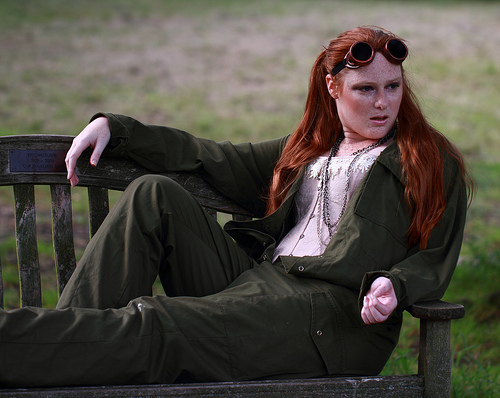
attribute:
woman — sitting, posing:
[2, 27, 468, 390]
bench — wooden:
[2, 131, 468, 396]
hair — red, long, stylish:
[259, 26, 475, 252]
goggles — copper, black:
[332, 37, 409, 74]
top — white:
[271, 153, 381, 268]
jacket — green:
[87, 112, 470, 379]